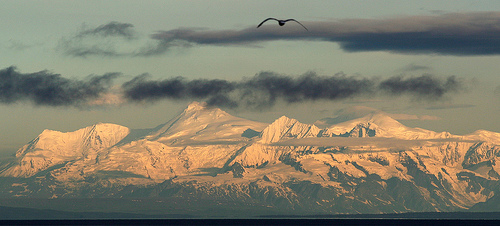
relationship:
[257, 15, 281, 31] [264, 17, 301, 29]
wing on bird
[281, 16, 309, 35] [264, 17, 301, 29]
wing on bird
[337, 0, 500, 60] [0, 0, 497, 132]
background in sky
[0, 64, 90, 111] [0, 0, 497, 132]
black clouds in sky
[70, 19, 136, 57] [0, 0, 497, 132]
cloud in sky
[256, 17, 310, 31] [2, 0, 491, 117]
bird in sky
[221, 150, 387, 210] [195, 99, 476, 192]
marks on snow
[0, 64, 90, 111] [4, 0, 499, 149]
black clouds in sky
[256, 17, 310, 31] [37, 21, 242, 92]
bird flying in sky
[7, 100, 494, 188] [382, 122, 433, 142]
light reflected on snow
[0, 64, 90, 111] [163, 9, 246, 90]
black clouds in sky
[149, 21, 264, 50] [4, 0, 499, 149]
cloud in sky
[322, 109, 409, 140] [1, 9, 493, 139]
mountain in background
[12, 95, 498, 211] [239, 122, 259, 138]
mountain has shadow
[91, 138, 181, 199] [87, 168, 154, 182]
mountain has shadow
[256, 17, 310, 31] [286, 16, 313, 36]
bird has wing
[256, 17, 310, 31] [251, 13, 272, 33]
bird has wing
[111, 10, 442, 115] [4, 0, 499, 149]
clouds in sky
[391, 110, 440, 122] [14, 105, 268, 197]
cloud covers mountain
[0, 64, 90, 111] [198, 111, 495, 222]
black clouds covers mountain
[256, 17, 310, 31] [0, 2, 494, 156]
bird in air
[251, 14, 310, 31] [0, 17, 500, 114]
bird in front of black clouds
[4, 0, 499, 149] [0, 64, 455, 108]
sky has cloud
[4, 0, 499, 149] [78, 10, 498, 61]
sky has cloud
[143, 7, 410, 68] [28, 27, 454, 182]
cloud in sky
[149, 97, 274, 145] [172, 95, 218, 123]
mountain has top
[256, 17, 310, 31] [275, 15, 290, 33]
bird has body